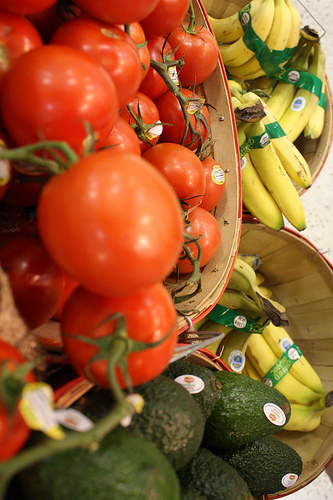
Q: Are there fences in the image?
A: No, there are no fences.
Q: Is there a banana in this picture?
A: Yes, there is a banana.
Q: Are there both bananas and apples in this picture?
A: No, there is a banana but no apples.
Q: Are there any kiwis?
A: No, there are no kiwis.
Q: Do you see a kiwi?
A: No, there are no kiwis.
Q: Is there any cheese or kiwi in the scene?
A: No, there are no kiwis or cheese.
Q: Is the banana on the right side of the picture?
A: Yes, the banana is on the right of the image.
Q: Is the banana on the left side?
A: No, the banana is on the right of the image.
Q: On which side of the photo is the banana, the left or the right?
A: The banana is on the right of the image.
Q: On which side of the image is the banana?
A: The banana is on the right of the image.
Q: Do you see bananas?
A: Yes, there is a banana.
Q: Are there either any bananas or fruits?
A: Yes, there is a banana.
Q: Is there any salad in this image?
A: No, there is no salad.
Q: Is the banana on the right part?
A: Yes, the banana is on the right of the image.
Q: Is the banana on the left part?
A: No, the banana is on the right of the image.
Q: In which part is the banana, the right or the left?
A: The banana is on the right of the image.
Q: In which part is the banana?
A: The banana is on the right of the image.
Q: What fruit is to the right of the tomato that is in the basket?
A: The fruit is a banana.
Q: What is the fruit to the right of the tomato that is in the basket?
A: The fruit is a banana.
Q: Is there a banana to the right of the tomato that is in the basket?
A: Yes, there is a banana to the right of the tomato.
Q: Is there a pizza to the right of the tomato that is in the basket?
A: No, there is a banana to the right of the tomato.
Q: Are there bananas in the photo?
A: Yes, there is a banana.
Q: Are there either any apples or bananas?
A: Yes, there is a banana.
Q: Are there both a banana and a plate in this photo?
A: No, there is a banana but no plates.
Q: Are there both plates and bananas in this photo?
A: No, there is a banana but no plates.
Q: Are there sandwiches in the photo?
A: No, there are no sandwiches.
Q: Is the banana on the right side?
A: Yes, the banana is on the right of the image.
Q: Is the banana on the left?
A: No, the banana is on the right of the image.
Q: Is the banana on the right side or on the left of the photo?
A: The banana is on the right of the image.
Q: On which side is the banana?
A: The banana is on the right of the image.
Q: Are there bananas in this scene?
A: Yes, there is a banana.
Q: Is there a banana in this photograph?
A: Yes, there is a banana.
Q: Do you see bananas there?
A: Yes, there is a banana.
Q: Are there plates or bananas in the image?
A: Yes, there is a banana.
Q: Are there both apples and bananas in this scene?
A: No, there is a banana but no apples.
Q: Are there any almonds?
A: No, there are no almonds.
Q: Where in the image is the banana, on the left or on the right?
A: The banana is on the right of the image.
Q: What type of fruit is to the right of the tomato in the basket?
A: The fruit is a banana.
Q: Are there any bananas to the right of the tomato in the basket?
A: Yes, there is a banana to the right of the tomato.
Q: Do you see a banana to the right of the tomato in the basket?
A: Yes, there is a banana to the right of the tomato.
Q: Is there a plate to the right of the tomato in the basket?
A: No, there is a banana to the right of the tomato.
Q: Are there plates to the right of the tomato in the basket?
A: No, there is a banana to the right of the tomato.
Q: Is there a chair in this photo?
A: No, there are no chairs.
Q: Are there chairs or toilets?
A: No, there are no chairs or toilets.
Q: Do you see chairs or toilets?
A: No, there are no chairs or toilets.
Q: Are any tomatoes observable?
A: Yes, there is a tomato.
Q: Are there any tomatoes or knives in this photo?
A: Yes, there is a tomato.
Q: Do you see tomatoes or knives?
A: Yes, there is a tomato.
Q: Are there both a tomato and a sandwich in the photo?
A: No, there is a tomato but no sandwiches.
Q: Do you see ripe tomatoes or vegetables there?
A: Yes, there is a ripe tomato.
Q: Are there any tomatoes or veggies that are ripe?
A: Yes, the tomato is ripe.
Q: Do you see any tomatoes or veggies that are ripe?
A: Yes, the tomato is ripe.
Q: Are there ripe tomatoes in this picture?
A: Yes, there is a ripe tomato.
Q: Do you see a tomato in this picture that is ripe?
A: Yes, there is a tomato that is ripe.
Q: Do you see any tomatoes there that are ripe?
A: Yes, there is a tomato that is ripe.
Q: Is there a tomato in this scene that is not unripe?
A: Yes, there is an ripe tomato.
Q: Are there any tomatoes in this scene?
A: Yes, there is a tomato.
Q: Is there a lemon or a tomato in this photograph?
A: Yes, there is a tomato.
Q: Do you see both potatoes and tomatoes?
A: No, there is a tomato but no potatoes.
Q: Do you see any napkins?
A: No, there are no napkins.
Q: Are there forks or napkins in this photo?
A: No, there are no napkins or forks.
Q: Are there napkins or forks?
A: No, there are no napkins or forks.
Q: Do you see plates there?
A: No, there are no plates.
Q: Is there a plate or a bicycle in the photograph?
A: No, there are no plates or bicycles.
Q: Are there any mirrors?
A: No, there are no mirrors.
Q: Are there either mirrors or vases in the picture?
A: No, there are no mirrors or vases.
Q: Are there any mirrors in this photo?
A: No, there are no mirrors.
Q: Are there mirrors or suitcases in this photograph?
A: No, there are no mirrors or suitcases.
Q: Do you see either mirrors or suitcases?
A: No, there are no mirrors or suitcases.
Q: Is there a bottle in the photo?
A: No, there are no bottles.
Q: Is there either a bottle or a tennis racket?
A: No, there are no bottles or rackets.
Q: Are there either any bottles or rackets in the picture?
A: No, there are no bottles or rackets.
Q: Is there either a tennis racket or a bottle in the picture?
A: No, there are no bottles or rackets.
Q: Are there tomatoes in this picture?
A: Yes, there is a tomato.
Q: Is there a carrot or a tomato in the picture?
A: Yes, there is a tomato.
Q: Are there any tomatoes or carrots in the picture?
A: Yes, there is a tomato.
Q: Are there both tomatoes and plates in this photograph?
A: No, there is a tomato but no plates.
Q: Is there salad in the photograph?
A: No, there is no salad.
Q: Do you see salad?
A: No, there is no salad.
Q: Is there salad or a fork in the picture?
A: No, there are no salad or forks.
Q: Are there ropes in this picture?
A: No, there are no ropes.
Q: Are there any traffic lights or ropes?
A: No, there are no ropes or traffic lights.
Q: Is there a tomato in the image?
A: Yes, there is a tomato.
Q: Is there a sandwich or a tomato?
A: Yes, there is a tomato.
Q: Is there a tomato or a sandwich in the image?
A: Yes, there is a tomato.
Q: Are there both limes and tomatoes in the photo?
A: No, there is a tomato but no limes.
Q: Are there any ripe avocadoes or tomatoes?
A: Yes, there is a ripe tomato.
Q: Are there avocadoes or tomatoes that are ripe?
A: Yes, the tomato is ripe.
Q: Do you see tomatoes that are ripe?
A: Yes, there is a ripe tomato.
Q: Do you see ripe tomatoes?
A: Yes, there is a ripe tomato.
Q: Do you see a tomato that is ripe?
A: Yes, there is a tomato that is ripe.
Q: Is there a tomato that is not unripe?
A: Yes, there is an ripe tomato.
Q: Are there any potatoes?
A: No, there are no potatoes.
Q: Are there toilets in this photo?
A: No, there are no toilets.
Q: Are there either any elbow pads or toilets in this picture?
A: No, there are no toilets or elbow pads.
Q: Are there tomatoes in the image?
A: Yes, there is a tomato.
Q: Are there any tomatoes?
A: Yes, there is a tomato.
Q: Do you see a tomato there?
A: Yes, there is a tomato.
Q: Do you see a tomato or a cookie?
A: Yes, there is a tomato.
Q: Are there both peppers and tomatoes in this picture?
A: No, there is a tomato but no peppers.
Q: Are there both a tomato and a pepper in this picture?
A: No, there is a tomato but no peppers.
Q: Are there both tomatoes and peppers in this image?
A: No, there is a tomato but no peppers.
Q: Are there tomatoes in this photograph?
A: Yes, there is a tomato.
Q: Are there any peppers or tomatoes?
A: Yes, there is a tomato.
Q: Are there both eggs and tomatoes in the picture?
A: No, there is a tomato but no eggs.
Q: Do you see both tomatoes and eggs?
A: No, there is a tomato but no eggs.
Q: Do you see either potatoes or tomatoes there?
A: Yes, there is a tomato.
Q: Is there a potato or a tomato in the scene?
A: Yes, there is a tomato.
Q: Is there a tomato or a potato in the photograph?
A: Yes, there is a tomato.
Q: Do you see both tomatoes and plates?
A: No, there is a tomato but no plates.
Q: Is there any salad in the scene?
A: No, there is no salad.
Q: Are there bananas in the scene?
A: Yes, there are bananas.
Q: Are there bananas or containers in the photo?
A: Yes, there are bananas.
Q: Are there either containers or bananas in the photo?
A: Yes, there are bananas.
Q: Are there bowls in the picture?
A: No, there are no bowls.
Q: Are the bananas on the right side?
A: Yes, the bananas are on the right of the image.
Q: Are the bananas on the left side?
A: No, the bananas are on the right of the image.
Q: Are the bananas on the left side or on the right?
A: The bananas are on the right of the image.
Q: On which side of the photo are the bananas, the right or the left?
A: The bananas are on the right of the image.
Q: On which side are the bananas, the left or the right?
A: The bananas are on the right of the image.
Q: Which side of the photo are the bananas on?
A: The bananas are on the right of the image.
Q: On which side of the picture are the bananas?
A: The bananas are on the right of the image.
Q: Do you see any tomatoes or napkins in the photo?
A: Yes, there is a tomato.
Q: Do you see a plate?
A: No, there are no plates.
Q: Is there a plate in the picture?
A: No, there are no plates.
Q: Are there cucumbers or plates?
A: No, there are no plates or cucumbers.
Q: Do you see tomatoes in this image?
A: Yes, there is a tomato.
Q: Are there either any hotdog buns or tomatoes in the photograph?
A: Yes, there is a tomato.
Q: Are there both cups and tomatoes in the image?
A: No, there is a tomato but no cups.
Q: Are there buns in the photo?
A: No, there are no buns.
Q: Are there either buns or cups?
A: No, there are no buns or cups.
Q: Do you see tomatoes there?
A: Yes, there is a tomato.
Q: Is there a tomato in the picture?
A: Yes, there is a tomato.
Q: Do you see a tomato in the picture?
A: Yes, there is a tomato.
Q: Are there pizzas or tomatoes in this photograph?
A: Yes, there is a tomato.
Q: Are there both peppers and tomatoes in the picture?
A: No, there is a tomato but no peppers.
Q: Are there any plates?
A: No, there are no plates.